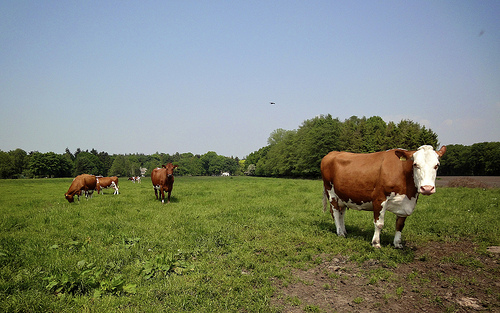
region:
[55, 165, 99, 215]
Black and white cow in the field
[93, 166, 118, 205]
Black and white cow in the field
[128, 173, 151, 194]
Black and white cow in the field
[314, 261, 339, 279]
Small patch of green grass in the mud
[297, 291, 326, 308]
Small patch of green grass in the mud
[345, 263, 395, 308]
Small patch of green grass in the mud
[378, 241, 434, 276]
Small patch of green grass in the mud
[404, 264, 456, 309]
Small patch of green grass in the mud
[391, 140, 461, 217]
the head of a cow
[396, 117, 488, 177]
the ear of a cow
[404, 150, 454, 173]
the eyes of a cow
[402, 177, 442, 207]
the mouth of a cow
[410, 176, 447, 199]
the nose of a cow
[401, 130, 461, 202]
the white head of a cow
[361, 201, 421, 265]
the legs of a cow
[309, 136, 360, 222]
the tail of a cow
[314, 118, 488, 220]
the body of a cow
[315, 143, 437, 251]
A brown and white cow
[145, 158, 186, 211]
A brown and white cow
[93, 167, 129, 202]
A brown and white cow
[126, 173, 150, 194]
A brown and white cow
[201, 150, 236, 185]
A short green thick tree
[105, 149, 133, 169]
A short green thick tree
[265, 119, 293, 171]
A short green thick tree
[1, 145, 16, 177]
A short green thick tree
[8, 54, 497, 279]
cows are in green field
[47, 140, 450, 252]
cows are in a field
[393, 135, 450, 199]
the cow has a white head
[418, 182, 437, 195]
a cow has a pink nose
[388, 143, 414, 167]
a tag is on the cow's ear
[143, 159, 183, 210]
a brown cow has a white foot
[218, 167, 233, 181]
a white cow is in the back field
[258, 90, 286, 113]
an object is in the air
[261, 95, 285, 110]
a black bird is in the air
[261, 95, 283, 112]
a plane is flying above the trees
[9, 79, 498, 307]
cows standing in a field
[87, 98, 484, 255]
cows walking in a field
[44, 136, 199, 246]
cows eating in a field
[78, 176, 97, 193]
cows eatting grass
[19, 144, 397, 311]
a field of grass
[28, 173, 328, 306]
a field of green grass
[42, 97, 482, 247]
cows walking on grass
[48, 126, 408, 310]
cows walking on green grass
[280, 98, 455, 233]
trees with leaves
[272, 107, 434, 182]
trees with green leaves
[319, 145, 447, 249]
a brown and white cow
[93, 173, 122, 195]
a brown and white cow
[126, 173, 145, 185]
a brown and white cow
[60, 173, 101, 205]
a brown cow eating grass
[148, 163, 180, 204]
a cow walking on grass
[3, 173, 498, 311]
a field of grass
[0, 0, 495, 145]
a clear blue sky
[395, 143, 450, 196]
the head of a cow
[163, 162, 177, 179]
the head of a cow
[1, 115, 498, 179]
trees with green leaves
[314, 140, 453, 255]
brown and white cow standing on the ground